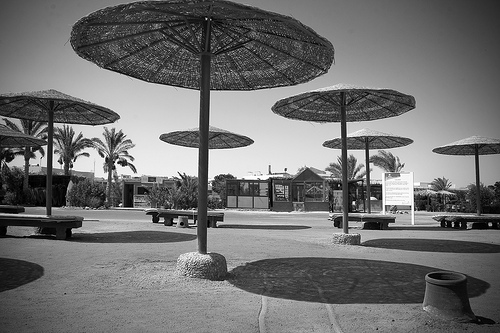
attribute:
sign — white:
[377, 169, 416, 226]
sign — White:
[382, 169, 416, 226]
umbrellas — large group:
[3, 37, 492, 217]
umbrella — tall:
[431, 132, 498, 158]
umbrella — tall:
[323, 127, 413, 148]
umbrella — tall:
[271, 82, 417, 122]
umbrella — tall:
[158, 123, 254, 151]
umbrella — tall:
[3, 87, 120, 130]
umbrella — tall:
[65, 3, 336, 92]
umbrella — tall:
[1, 127, 47, 149]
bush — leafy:
[141, 172, 221, 209]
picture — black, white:
[9, 10, 495, 327]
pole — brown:
[187, 22, 214, 257]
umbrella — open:
[271, 84, 418, 124]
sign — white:
[370, 164, 436, 236]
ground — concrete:
[6, 206, 498, 331]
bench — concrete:
[0, 214, 83, 236]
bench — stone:
[325, 208, 398, 232]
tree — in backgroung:
[96, 130, 138, 201]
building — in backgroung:
[252, 164, 340, 211]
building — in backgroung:
[118, 163, 173, 210]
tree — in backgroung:
[51, 125, 86, 212]